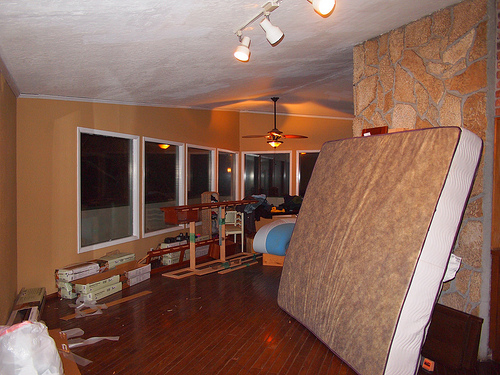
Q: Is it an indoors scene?
A: Yes, it is indoors.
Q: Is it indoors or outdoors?
A: It is indoors.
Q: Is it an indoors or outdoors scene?
A: It is indoors.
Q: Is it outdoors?
A: No, it is indoors.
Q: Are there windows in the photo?
A: Yes, there is a window.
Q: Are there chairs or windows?
A: Yes, there is a window.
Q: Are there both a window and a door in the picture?
A: No, there is a window but no doors.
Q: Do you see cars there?
A: No, there are no cars.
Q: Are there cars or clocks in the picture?
A: No, there are no cars or clocks.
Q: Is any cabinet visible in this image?
A: No, there are no cabinets.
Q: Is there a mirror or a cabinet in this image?
A: No, there are no cabinets or mirrors.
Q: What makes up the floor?
A: The floor is made of wood.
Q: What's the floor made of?
A: The floor is made of wood.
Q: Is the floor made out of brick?
A: No, the floor is made of wood.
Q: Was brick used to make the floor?
A: No, the floor is made of wood.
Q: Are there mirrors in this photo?
A: No, there are no mirrors.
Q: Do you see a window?
A: Yes, there is a window.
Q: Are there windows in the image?
A: Yes, there is a window.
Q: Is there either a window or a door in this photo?
A: Yes, there is a window.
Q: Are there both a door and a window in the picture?
A: No, there is a window but no doors.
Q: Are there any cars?
A: No, there are no cars.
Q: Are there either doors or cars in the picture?
A: No, there are no cars or doors.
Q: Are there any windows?
A: Yes, there is a window.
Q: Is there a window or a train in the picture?
A: Yes, there is a window.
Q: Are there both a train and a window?
A: No, there is a window but no trains.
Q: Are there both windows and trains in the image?
A: No, there is a window but no trains.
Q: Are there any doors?
A: No, there are no doors.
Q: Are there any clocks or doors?
A: No, there are no doors or clocks.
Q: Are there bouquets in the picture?
A: No, there are no bouquets.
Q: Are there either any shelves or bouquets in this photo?
A: No, there are no bouquets or shelves.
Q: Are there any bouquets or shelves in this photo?
A: No, there are no bouquets or shelves.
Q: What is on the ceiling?
A: The fan is on the ceiling.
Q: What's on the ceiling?
A: The fan is on the ceiling.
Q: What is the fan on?
A: The fan is on the ceiling.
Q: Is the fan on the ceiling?
A: Yes, the fan is on the ceiling.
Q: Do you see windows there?
A: Yes, there is a window.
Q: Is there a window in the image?
A: Yes, there is a window.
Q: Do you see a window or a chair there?
A: Yes, there is a window.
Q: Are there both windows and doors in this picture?
A: No, there is a window but no doors.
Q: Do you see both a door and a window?
A: No, there is a window but no doors.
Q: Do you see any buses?
A: No, there are no buses.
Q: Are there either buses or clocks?
A: No, there are no buses or clocks.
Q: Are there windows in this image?
A: Yes, there is a window.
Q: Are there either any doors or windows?
A: Yes, there is a window.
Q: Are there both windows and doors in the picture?
A: No, there is a window but no doors.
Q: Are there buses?
A: No, there are no buses.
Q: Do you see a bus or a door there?
A: No, there are no buses or doors.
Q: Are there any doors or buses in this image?
A: No, there are no buses or doors.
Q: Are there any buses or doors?
A: No, there are no buses or doors.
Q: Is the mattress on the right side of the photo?
A: Yes, the mattress is on the right of the image.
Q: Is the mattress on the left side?
A: No, the mattress is on the right of the image.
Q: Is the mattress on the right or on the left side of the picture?
A: The mattress is on the right of the image.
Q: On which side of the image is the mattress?
A: The mattress is on the right of the image.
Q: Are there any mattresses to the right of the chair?
A: Yes, there is a mattress to the right of the chair.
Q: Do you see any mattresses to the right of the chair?
A: Yes, there is a mattress to the right of the chair.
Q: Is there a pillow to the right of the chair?
A: No, there is a mattress to the right of the chair.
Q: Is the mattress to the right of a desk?
A: No, the mattress is to the right of the chair.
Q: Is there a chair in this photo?
A: Yes, there is a chair.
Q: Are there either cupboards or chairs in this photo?
A: Yes, there is a chair.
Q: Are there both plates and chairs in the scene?
A: No, there is a chair but no plates.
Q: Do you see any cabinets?
A: No, there are no cabinets.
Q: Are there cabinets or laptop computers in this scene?
A: No, there are no cabinets or laptop computers.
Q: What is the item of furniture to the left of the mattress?
A: The piece of furniture is a chair.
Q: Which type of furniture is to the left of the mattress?
A: The piece of furniture is a chair.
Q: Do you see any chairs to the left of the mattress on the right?
A: Yes, there is a chair to the left of the mattress.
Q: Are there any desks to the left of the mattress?
A: No, there is a chair to the left of the mattress.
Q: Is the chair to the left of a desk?
A: No, the chair is to the left of the mattress.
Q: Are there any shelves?
A: No, there are no shelves.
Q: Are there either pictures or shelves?
A: No, there are no shelves or pictures.